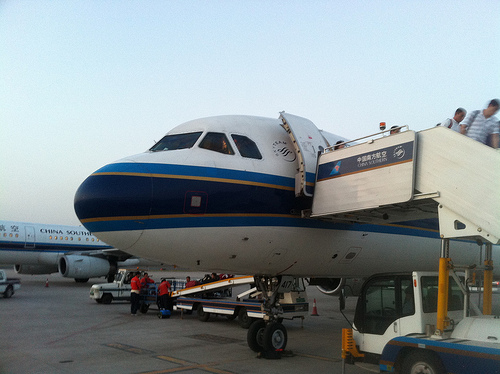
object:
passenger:
[333, 98, 500, 152]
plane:
[73, 111, 500, 354]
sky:
[85, 36, 177, 89]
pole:
[435, 238, 450, 335]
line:
[150, 353, 235, 374]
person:
[441, 108, 466, 137]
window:
[197, 131, 263, 160]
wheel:
[246, 319, 288, 354]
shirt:
[460, 109, 500, 144]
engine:
[56, 256, 120, 279]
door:
[278, 110, 335, 199]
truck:
[361, 276, 468, 369]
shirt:
[158, 281, 171, 296]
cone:
[311, 298, 320, 317]